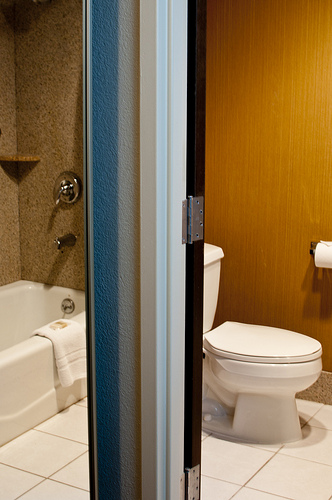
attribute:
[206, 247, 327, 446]
toilet — white, porcelain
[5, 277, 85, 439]
tub — white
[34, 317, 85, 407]
towel — white, here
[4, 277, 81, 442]
bathtub — white, here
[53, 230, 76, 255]
faucet — silver, all-in-one, shower's, chrome, here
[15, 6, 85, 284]
wall — tub's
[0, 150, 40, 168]
shelf — shower's, corner shelf, mini, here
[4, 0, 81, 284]
wall — granite, marble, shower's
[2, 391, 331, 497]
tile — white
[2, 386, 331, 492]
floor — bathrooms's, tile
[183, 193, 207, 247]
hinge — silver, door hinge, door's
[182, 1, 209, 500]
door — brown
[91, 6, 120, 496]
line — blue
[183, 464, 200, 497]
hinge — silver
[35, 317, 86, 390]
bathmat — white, hanging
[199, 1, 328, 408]
wall — orange, yellow, bathroom's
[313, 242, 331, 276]
toilet tissue — hanging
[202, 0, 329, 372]
panel — wood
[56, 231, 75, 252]
pipe — silver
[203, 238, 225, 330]
tank — white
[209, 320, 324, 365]
toilet cover — white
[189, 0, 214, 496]
toilet door — black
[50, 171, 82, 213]
knob — here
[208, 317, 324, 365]
toilet seat — down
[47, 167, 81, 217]
hot knob — here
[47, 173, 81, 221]
cold knob — here